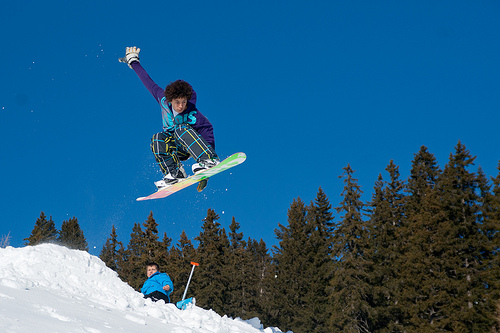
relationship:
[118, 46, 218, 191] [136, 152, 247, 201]
boy on snowboard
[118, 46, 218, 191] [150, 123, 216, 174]
boy wearing pants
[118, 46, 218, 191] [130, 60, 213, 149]
boy wearing sweatshirt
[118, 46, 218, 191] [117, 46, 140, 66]
boy wearing glove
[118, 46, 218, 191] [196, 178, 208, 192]
boy wearing glove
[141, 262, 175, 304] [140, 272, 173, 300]
man wearing jacket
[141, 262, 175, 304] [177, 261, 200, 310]
man next to handle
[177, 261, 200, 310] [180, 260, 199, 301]
handle has handle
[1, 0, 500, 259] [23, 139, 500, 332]
sky above trees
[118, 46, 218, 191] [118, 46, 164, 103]
boy has arm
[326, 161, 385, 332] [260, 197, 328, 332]
tree next to tree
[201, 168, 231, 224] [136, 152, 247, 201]
snow falling down from snowboard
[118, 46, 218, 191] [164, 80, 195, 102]
boy has hair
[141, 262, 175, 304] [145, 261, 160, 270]
man has hair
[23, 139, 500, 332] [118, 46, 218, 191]
trees are behind boy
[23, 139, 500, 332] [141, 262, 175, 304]
trees are behind man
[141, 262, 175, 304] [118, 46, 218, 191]
man watching boy